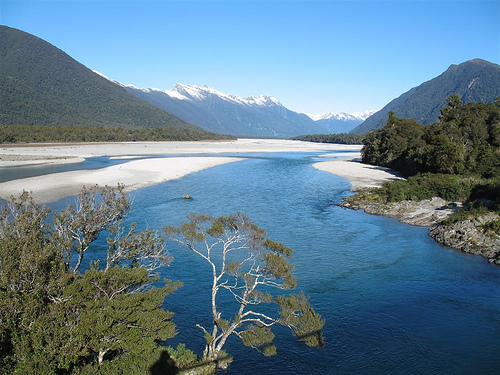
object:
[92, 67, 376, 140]
peaks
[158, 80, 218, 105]
snow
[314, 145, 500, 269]
line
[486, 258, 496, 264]
rocks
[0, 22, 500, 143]
mountain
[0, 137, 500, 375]
river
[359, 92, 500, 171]
tree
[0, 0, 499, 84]
clouds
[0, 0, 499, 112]
sky